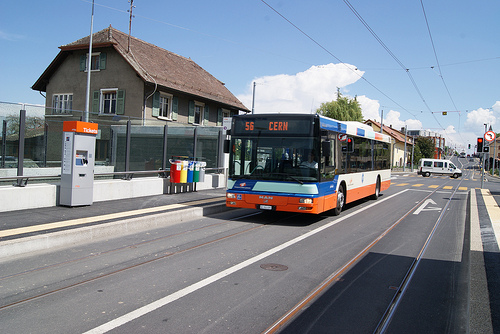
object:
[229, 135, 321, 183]
window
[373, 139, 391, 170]
window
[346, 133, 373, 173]
window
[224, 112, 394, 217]
bus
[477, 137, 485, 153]
light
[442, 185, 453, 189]
yellow lines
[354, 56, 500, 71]
cables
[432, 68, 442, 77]
wires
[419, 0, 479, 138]
wires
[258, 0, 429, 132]
wires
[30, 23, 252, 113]
roof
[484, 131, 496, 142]
traffic sign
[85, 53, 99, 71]
window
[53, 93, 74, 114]
window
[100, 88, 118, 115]
window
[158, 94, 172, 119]
window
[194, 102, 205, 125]
window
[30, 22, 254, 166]
building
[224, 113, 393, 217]
clock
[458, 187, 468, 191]
stripe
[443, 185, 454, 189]
stripe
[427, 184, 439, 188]
stripe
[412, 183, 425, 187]
stripe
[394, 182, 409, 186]
stripe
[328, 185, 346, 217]
wheel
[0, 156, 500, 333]
road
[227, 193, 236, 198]
headlight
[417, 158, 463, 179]
car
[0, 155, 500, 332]
ground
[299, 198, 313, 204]
headlight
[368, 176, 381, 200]
wheel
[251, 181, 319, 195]
stripe